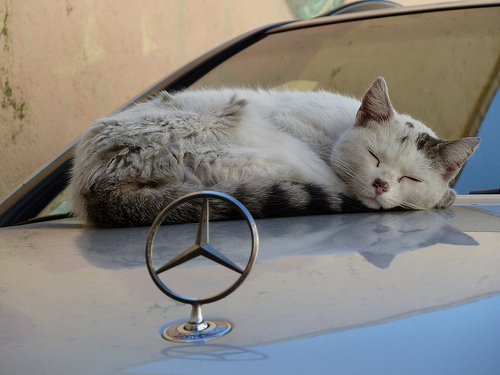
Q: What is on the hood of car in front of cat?
A: Round metallic grey insignia.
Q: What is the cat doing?
A: Asleep.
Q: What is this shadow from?
A: The insignia.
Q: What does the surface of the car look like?
A: Blue.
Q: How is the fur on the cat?
A: Light grey.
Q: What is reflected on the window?
A: Door of a car.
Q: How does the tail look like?
A: Grey and black.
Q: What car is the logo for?
A: Mercedes.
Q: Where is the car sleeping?
A: On the hood.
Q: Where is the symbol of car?
A: Hood.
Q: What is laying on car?
A: Cat.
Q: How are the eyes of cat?
A: Closed.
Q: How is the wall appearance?
A: Dirty.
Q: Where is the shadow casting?
A: Hood of car.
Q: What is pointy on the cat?
A: Ears.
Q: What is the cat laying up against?
A: Windshield.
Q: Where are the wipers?
A: Under cat.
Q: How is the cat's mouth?
A: Closed.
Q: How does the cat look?
A: Furry.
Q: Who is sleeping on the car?
A: The cat.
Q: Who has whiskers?
A: The cat.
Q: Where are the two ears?
A: On the cat's head.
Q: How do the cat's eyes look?
A: Closed.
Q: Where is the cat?
A: On the car.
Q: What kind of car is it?
A: Mercedes.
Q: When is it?
A: During the day.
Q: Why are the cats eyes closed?
A: It is sleeping.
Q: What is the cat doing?
A: Sleeping.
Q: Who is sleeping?
A: The cat.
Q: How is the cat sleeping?
A: Curled up.